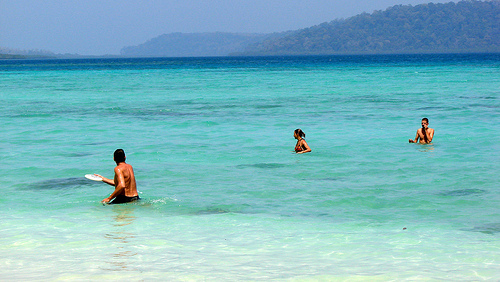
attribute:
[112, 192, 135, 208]
trunks — black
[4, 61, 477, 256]
water — blue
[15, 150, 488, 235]
shapes — dark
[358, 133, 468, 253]
water — ocean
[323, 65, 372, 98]
water — blue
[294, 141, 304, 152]
swimsuit — black and red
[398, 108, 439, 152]
man — young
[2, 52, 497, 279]
water — blue, turquoise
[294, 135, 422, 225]
water — blue